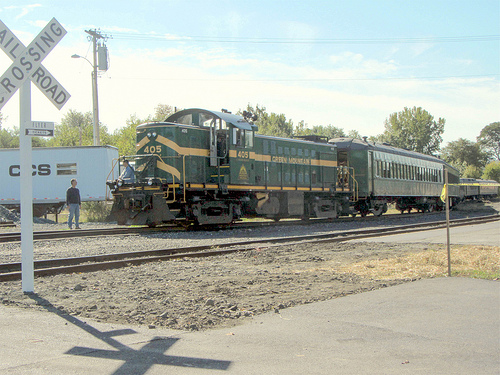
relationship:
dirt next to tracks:
[5, 242, 495, 329] [0, 207, 500, 282]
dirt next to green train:
[5, 242, 495, 329] [105, 105, 500, 228]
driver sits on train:
[113, 160, 134, 185] [103, 107, 465, 227]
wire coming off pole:
[110, 73, 498, 78] [70, 25, 117, 147]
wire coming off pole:
[107, 30, 499, 41] [70, 25, 117, 147]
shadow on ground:
[64, 318, 199, 369] [73, 275, 496, 373]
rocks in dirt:
[144, 288, 241, 329] [0, 240, 402, 331]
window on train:
[377, 161, 379, 176] [119, 94, 497, 215]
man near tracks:
[65, 177, 82, 227] [2, 207, 452, 242]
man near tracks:
[65, 177, 82, 227] [0, 207, 500, 282]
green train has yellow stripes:
[106, 109, 498, 236] [132, 136, 339, 193]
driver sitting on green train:
[113, 160, 134, 185] [105, 105, 500, 228]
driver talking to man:
[113, 160, 134, 185] [65, 177, 82, 227]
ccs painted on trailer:
[8, 161, 52, 177] [2, 134, 119, 220]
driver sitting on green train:
[108, 158, 133, 195] [105, 105, 500, 228]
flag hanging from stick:
[442, 183, 452, 203] [433, 166, 463, 273]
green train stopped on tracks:
[105, 105, 500, 228] [0, 205, 452, 244]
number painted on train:
[144, 145, 162, 153] [94, 102, 496, 218]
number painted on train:
[148, 143, 156, 153] [94, 102, 496, 218]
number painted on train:
[235, 150, 242, 157] [94, 102, 496, 218]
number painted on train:
[238, 151, 249, 159] [94, 102, 496, 218]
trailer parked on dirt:
[0, 144, 119, 205] [1, 217, 131, 237]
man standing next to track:
[66, 178, 82, 229] [1, 206, 459, 239]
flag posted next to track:
[440, 183, 447, 203] [1, 209, 481, 282]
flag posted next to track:
[440, 183, 447, 203] [1, 205, 455, 244]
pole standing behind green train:
[70, 25, 117, 147] [105, 105, 500, 228]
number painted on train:
[144, 145, 162, 153] [105, 109, 349, 234]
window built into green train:
[377, 161, 379, 176] [105, 105, 500, 228]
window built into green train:
[378, 151, 382, 178] [105, 105, 500, 228]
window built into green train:
[381, 152, 386, 176] [105, 105, 500, 228]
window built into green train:
[385, 154, 390, 178] [105, 105, 500, 228]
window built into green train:
[244, 131, 254, 148] [105, 105, 500, 228]